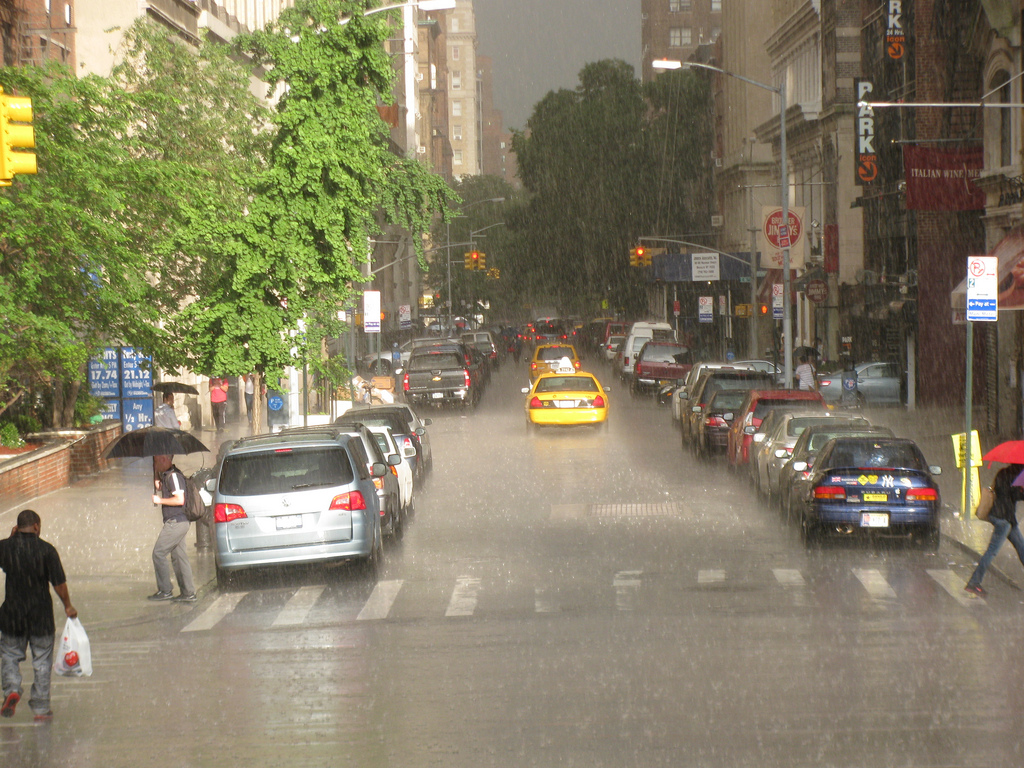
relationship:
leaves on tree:
[104, 4, 455, 378] [2, 1, 446, 460]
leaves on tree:
[176, 173, 378, 275] [81, 33, 434, 397]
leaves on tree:
[135, 44, 213, 151] [57, 24, 390, 368]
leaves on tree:
[316, 24, 397, 124] [40, 41, 473, 413]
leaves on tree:
[571, 67, 643, 178] [537, 78, 659, 297]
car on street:
[180, 404, 397, 586] [135, 569, 889, 708]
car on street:
[798, 428, 940, 554] [524, 424, 898, 720]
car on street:
[765, 415, 878, 496] [487, 426, 805, 692]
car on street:
[504, 353, 604, 429] [457, 398, 764, 721]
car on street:
[515, 331, 582, 375] [487, 396, 743, 699]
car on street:
[385, 335, 496, 413] [487, 396, 743, 699]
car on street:
[616, 325, 686, 392] [420, 419, 803, 716]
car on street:
[625, 342, 693, 401] [457, 398, 764, 721]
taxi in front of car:
[515, 331, 598, 375] [504, 353, 616, 432]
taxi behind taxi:
[524, 385, 631, 457] [515, 307, 609, 374]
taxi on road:
[524, 385, 631, 457] [474, 415, 738, 720]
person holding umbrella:
[135, 435, 224, 626] [68, 398, 235, 459]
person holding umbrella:
[135, 435, 223, 626] [96, 404, 218, 471]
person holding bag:
[4, 497, 95, 744] [45, 603, 117, 705]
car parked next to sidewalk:
[180, 404, 397, 586] [0, 372, 333, 757]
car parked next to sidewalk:
[798, 428, 940, 554] [810, 348, 1020, 550]